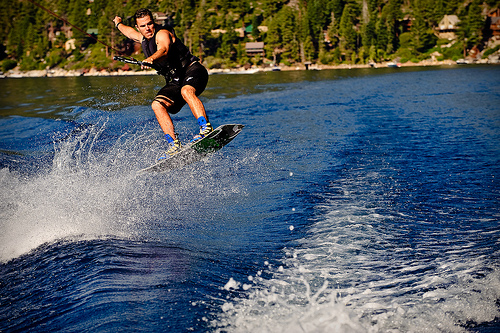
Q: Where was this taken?
A: Lake.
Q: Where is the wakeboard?
A: On the man's feet.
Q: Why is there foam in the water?
A: Boat's wake.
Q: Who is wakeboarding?
A: Man.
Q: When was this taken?
A: Daytime.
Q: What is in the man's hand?
A: Handle.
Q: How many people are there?
A: 1.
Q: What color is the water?
A: Blue.